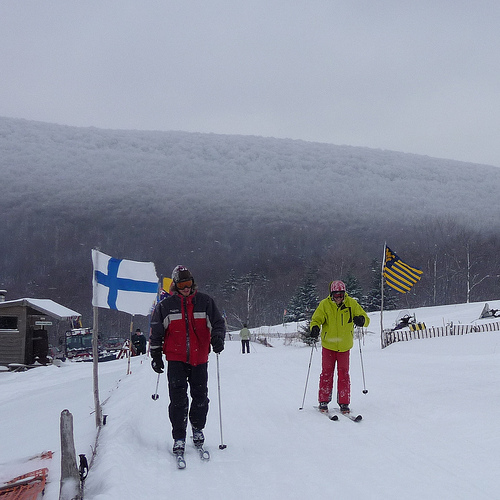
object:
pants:
[318, 347, 350, 404]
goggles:
[175, 279, 192, 290]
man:
[148, 265, 226, 454]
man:
[310, 280, 370, 413]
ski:
[190, 436, 211, 463]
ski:
[334, 408, 363, 422]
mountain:
[4, 100, 499, 343]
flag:
[381, 243, 424, 293]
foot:
[319, 402, 328, 414]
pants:
[167, 361, 209, 440]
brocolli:
[0, 115, 500, 261]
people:
[133, 329, 146, 356]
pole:
[358, 328, 368, 395]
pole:
[299, 344, 314, 409]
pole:
[216, 354, 227, 450]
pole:
[152, 373, 160, 401]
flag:
[91, 249, 160, 316]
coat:
[148, 288, 225, 365]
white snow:
[3, 299, 499, 500]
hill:
[3, 301, 499, 499]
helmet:
[330, 280, 346, 303]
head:
[331, 280, 346, 305]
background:
[1, 62, 500, 348]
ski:
[313, 406, 338, 420]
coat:
[310, 291, 370, 352]